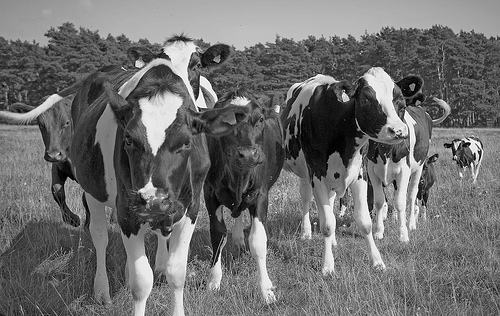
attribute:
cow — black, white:
[437, 131, 489, 192]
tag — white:
[130, 53, 151, 71]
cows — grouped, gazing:
[35, 34, 489, 314]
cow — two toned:
[268, 53, 415, 283]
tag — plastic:
[212, 53, 224, 65]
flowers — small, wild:
[428, 196, 464, 223]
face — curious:
[222, 102, 278, 167]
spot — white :
[135, 164, 162, 214]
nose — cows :
[129, 170, 169, 212]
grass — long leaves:
[386, 239, 488, 309]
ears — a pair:
[89, 71, 241, 144]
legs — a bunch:
[282, 181, 442, 278]